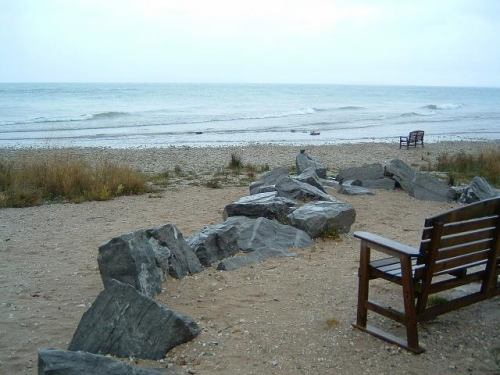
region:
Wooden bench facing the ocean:
[342, 192, 499, 353]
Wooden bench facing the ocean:
[392, 129, 424, 148]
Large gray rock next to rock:
[91, 221, 203, 296]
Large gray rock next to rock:
[61, 276, 199, 358]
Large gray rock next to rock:
[287, 195, 359, 237]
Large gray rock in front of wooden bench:
[99, 216, 209, 298]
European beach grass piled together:
[1, 153, 147, 208]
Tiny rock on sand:
[265, 350, 280, 367]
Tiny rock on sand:
[30, 320, 39, 329]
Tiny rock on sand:
[217, 282, 227, 295]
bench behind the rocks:
[357, 202, 498, 348]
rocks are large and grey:
[71, 130, 475, 371]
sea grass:
[18, 141, 184, 232]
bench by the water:
[394, 126, 476, 168]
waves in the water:
[258, 87, 355, 116]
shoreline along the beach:
[66, 124, 391, 154]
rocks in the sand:
[330, 295, 475, 367]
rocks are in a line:
[110, 138, 364, 373]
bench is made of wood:
[370, 234, 499, 347]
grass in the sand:
[418, 273, 480, 311]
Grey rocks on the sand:
[187, 182, 335, 280]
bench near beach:
[345, 95, 475, 170]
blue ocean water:
[113, 77, 340, 144]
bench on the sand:
[341, 180, 497, 330]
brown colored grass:
[20, 156, 165, 216]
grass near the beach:
[26, 105, 188, 221]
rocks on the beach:
[140, 81, 425, 286]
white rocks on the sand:
[201, 301, 376, 371]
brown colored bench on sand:
[330, 180, 498, 355]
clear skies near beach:
[51, 12, 378, 172]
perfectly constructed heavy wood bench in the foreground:
[350, 193, 498, 354]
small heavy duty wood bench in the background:
[397, 128, 425, 150]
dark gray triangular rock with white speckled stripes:
[67, 275, 200, 360]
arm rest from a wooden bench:
[352, 229, 420, 260]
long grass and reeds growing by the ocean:
[0, 155, 169, 208]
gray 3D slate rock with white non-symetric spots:
[95, 221, 204, 296]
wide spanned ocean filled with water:
[0, 83, 499, 150]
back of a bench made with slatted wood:
[412, 197, 499, 282]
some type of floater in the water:
[305, 127, 323, 139]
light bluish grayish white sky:
[0, 0, 499, 87]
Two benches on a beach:
[352, 128, 498, 358]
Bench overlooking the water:
[379, 54, 463, 160]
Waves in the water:
[2, 97, 472, 127]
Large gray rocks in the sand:
[34, 145, 499, 362]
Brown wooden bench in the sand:
[350, 193, 498, 357]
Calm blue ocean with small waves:
[2, 65, 499, 149]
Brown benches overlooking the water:
[334, 84, 499, 348]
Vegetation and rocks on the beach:
[0, 133, 499, 213]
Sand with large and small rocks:
[4, 209, 499, 374]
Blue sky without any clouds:
[2, 0, 498, 93]